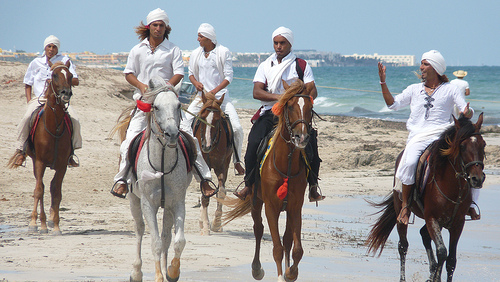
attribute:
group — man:
[16, 9, 486, 224]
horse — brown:
[24, 58, 75, 233]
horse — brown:
[363, 109, 490, 280]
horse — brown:
[216, 79, 319, 280]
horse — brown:
[182, 88, 240, 229]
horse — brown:
[10, 57, 75, 237]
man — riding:
[116, 14, 226, 244]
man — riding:
[18, 41, 108, 132]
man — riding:
[235, 8, 350, 153]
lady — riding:
[382, 51, 497, 220]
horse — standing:
[125, 85, 218, 272]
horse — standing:
[34, 66, 132, 270]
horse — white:
[127, 85, 199, 215]